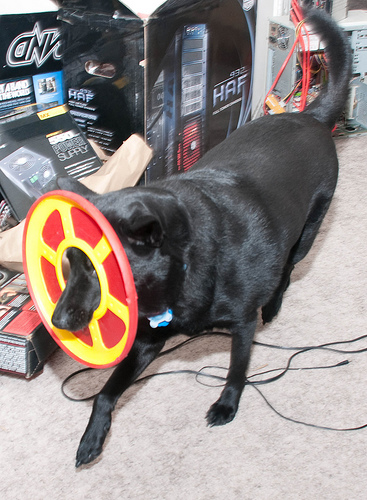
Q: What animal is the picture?
A: A black colored dog.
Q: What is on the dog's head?
A: A frisbee.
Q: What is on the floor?
A: Black electrical wire.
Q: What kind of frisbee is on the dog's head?
A: A yellow and red frisbee.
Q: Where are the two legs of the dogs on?
A: They're on the floor.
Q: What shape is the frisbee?
A: Round.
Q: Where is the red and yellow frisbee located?
A: On top of the dog's head.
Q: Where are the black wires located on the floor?
A: Under the dog's legs.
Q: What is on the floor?
A: Black wire.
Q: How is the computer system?
A: Case off.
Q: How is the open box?
A: Black.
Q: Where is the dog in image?
A: Walking on carpet.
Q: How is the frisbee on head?
A: Dog.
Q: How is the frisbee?
A: Red and yellow frisbee.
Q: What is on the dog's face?
A: Frisbee.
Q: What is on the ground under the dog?
A: Cords.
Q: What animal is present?
A: Dog.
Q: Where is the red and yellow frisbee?
A: Dog's mouth.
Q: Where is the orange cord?
A: Behind dog.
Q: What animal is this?
A: Dog.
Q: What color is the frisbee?
A: Yellow and red.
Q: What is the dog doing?
A: Playing.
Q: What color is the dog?
A: Black.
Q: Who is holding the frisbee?
A: Dog.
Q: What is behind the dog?
A: Boxes.